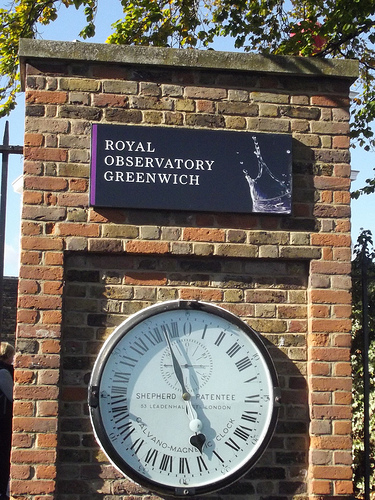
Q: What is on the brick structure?
A: A clock.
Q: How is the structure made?
A: Bricks and mortar.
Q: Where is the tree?
A: Above the structure.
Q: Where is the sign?
A: On the bricks.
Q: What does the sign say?
A: Royal observatory greenwich.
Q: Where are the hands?
A: On the clock.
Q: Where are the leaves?
A: On the tree.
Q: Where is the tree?
A: Behind the bricks.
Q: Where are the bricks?
A: In the structure.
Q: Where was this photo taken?
A: England.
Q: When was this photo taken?
A: During daylight hours.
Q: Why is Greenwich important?
A: Greenwich is used for world timekeeping.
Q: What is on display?
A: Greenwich Mean Time.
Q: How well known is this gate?
A: The gate is very famous.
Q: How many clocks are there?
A: One.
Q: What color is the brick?
A: Brown and red.